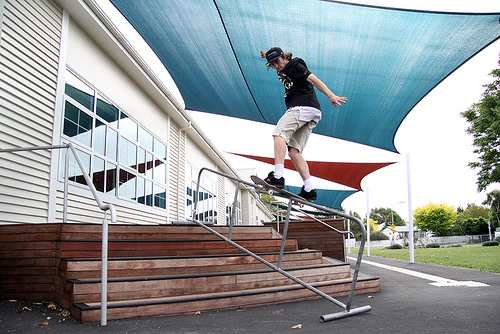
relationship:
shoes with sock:
[256, 171, 318, 201] [266, 158, 286, 179]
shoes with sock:
[256, 171, 318, 201] [298, 177, 318, 193]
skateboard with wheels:
[243, 175, 315, 210] [259, 182, 309, 217]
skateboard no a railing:
[250, 174, 316, 208] [186, 156, 376, 316]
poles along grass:
[352, 143, 426, 268] [351, 222, 496, 283]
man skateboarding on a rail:
[257, 47, 348, 204] [168, 154, 378, 324]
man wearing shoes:
[252, 43, 325, 188] [254, 165, 325, 199]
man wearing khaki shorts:
[257, 47, 348, 204] [271, 105, 322, 155]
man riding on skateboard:
[257, 47, 348, 204] [247, 170, 319, 207]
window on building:
[59, 75, 176, 206] [30, 7, 200, 240]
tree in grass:
[415, 173, 492, 238] [381, 239, 483, 263]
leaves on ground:
[4, 296, 75, 326] [1, 305, 133, 332]